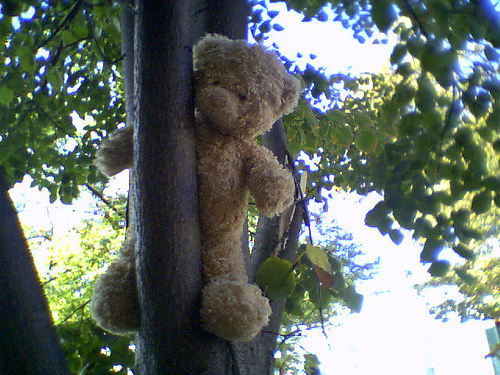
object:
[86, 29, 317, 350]
teddy bear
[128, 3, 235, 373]
tree branch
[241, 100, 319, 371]
tree branch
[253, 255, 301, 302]
leaf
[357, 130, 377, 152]
leaf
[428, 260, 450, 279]
leaf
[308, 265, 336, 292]
leaf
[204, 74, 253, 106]
eyes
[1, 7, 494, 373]
tree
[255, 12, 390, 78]
sky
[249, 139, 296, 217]
left arm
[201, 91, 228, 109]
nose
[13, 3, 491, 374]
shade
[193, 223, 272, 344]
leg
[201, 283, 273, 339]
foot